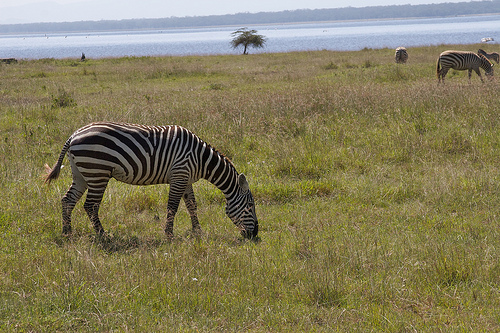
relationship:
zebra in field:
[50, 120, 265, 242] [11, 57, 497, 325]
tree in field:
[232, 26, 261, 54] [11, 57, 497, 325]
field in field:
[0, 42, 497, 333] [11, 57, 497, 325]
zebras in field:
[384, 39, 497, 96] [11, 57, 497, 325]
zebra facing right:
[50, 120, 265, 242] [276, 10, 488, 326]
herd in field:
[29, 44, 496, 158] [11, 57, 497, 325]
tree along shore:
[232, 26, 261, 54] [70, 28, 461, 61]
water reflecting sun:
[41, 24, 419, 44] [6, 2, 65, 17]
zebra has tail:
[50, 120, 265, 242] [39, 134, 93, 175]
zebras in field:
[384, 39, 497, 96] [0, 42, 497, 333]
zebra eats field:
[50, 120, 265, 242] [0, 42, 497, 333]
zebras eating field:
[384, 39, 497, 96] [0, 42, 497, 333]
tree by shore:
[232, 26, 261, 54] [70, 28, 461, 61]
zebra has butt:
[50, 120, 265, 242] [59, 128, 105, 163]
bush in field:
[57, 80, 93, 124] [0, 42, 497, 333]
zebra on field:
[50, 120, 265, 242] [0, 42, 497, 333]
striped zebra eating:
[90, 134, 205, 171] [234, 211, 287, 249]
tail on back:
[39, 134, 93, 175] [63, 115, 131, 156]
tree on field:
[232, 26, 261, 54] [0, 42, 497, 333]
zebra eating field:
[50, 120, 265, 242] [0, 42, 497, 333]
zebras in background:
[384, 39, 497, 96] [217, 11, 471, 93]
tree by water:
[232, 26, 261, 54] [41, 24, 419, 44]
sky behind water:
[7, 1, 307, 22] [41, 24, 419, 44]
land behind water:
[53, 0, 465, 25] [0, 14, 500, 58]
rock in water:
[478, 34, 499, 47] [41, 24, 419, 44]